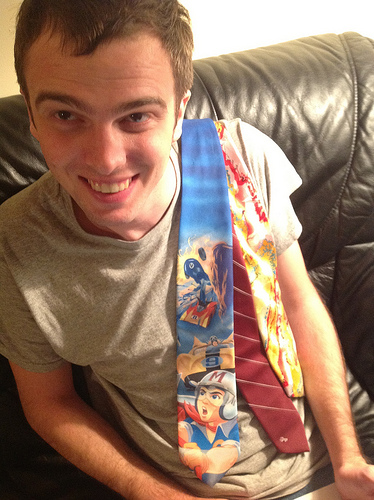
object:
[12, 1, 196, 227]
head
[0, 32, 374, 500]
couch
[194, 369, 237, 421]
helmet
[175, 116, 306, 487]
design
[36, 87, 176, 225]
smiling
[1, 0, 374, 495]
man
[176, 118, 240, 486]
tie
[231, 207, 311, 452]
tie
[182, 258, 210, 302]
bird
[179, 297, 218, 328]
race car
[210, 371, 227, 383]
letter "m"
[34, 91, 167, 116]
eye brows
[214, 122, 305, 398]
tie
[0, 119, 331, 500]
shirt